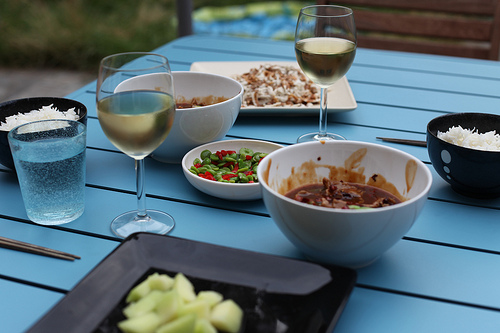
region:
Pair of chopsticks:
[0, 235, 80, 262]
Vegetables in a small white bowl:
[181, 138, 291, 199]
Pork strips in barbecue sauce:
[258, 140, 430, 267]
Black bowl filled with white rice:
[425, 110, 499, 193]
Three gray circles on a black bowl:
[436, 146, 455, 182]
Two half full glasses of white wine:
[92, 3, 355, 239]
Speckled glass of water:
[8, 118, 87, 226]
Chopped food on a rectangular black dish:
[11, 230, 357, 330]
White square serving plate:
[185, 59, 358, 114]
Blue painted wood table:
[1, 30, 498, 332]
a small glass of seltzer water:
[6, 125, 98, 225]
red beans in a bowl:
[280, 171, 412, 213]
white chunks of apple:
[140, 274, 227, 331]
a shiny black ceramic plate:
[251, 267, 326, 322]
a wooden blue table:
[414, 215, 488, 312]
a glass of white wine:
[103, 55, 184, 237]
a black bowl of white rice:
[5, 98, 79, 118]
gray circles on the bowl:
[437, 150, 454, 178]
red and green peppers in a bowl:
[192, 148, 265, 187]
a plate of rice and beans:
[235, 55, 300, 102]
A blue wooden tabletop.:
[2, 29, 499, 331]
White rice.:
[434, 117, 498, 156]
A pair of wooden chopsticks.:
[0, 236, 82, 268]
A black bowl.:
[426, 107, 498, 199]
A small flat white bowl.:
[183, 140, 283, 198]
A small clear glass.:
[12, 121, 82, 225]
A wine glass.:
[97, 50, 180, 237]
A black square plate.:
[18, 230, 360, 329]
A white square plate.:
[192, 57, 356, 112]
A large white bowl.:
[258, 134, 433, 264]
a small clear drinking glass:
[9, 115, 90, 226]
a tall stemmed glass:
[96, 50, 180, 239]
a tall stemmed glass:
[292, 0, 358, 142]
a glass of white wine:
[294, 2, 355, 143]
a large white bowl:
[252, 138, 432, 273]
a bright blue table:
[0, 33, 497, 330]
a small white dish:
[178, 135, 287, 200]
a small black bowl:
[422, 112, 497, 202]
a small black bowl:
[0, 92, 85, 172]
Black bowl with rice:
[425, 111, 499, 199]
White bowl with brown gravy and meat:
[257, 139, 433, 271]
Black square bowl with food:
[24, 230, 357, 332]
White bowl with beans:
[181, 139, 287, 201]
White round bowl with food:
[113, 71, 243, 164]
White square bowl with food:
[189, 59, 358, 111]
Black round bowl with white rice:
[0, 96, 87, 170]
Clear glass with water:
[7, 117, 87, 225]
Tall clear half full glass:
[95, 51, 176, 240]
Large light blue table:
[0, 32, 499, 332]